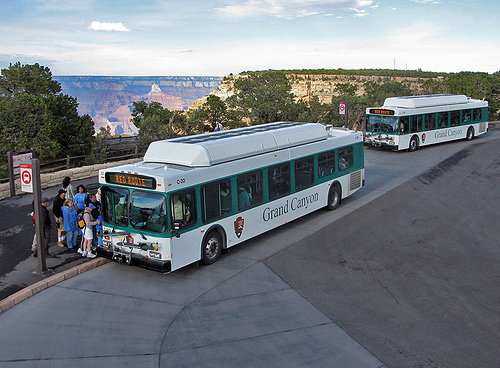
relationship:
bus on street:
[86, 118, 370, 276] [2, 128, 391, 297]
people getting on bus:
[28, 173, 105, 257] [86, 118, 370, 276]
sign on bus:
[232, 215, 247, 240] [86, 118, 370, 276]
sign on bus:
[421, 132, 428, 142] [361, 92, 494, 154]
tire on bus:
[198, 229, 226, 266] [86, 118, 370, 276]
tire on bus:
[326, 182, 344, 211] [86, 118, 370, 276]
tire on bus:
[408, 137, 417, 152] [361, 92, 494, 154]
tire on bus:
[466, 126, 477, 139] [361, 92, 494, 154]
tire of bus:
[198, 229, 226, 266] [86, 118, 370, 276]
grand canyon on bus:
[263, 191, 323, 224] [86, 118, 370, 276]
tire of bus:
[326, 182, 344, 211] [86, 118, 370, 276]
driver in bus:
[157, 193, 195, 229] [86, 118, 370, 276]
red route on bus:
[111, 173, 147, 189] [86, 118, 370, 276]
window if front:
[98, 184, 170, 236] [91, 169, 173, 272]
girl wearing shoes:
[77, 202, 103, 262] [87, 251, 96, 261]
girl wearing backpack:
[77, 202, 103, 262] [75, 213, 88, 231]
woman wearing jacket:
[59, 197, 80, 250] [59, 205, 80, 232]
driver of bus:
[157, 193, 195, 229] [86, 118, 370, 276]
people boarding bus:
[28, 173, 105, 257] [86, 118, 370, 276]